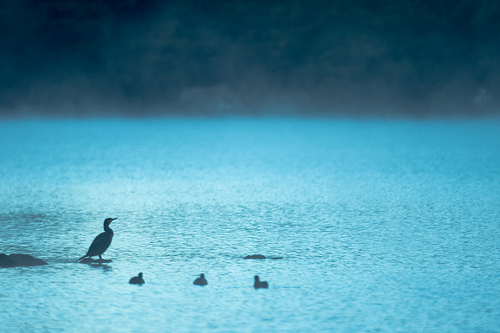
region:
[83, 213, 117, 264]
a duck standing in the water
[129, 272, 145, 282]
a duck sitting in the water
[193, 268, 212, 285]
a duck sitting in the water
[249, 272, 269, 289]
a duck sitting in the water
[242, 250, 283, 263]
a rock in the water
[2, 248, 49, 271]
a rock in the water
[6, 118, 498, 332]
bright blue body of water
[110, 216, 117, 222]
the beak of the duck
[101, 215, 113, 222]
the head of the duck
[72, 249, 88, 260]
the tail of the duck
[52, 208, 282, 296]
Four ducks are in the picture.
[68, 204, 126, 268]
The adult duck is standing on a rock.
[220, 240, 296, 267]
A few rocks are in the water.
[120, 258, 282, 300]
Three ducks are swimming.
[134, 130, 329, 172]
The water is blue.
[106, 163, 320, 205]
The light is reflecting on the water.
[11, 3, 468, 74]
Trees are in the background.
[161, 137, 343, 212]
The water is clear.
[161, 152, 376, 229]
The water is bright.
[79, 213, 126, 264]
grown up duck standing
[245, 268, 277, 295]
baby duck in the water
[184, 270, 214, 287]
baby duck in the water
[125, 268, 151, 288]
baby duck in the water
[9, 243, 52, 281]
rock sitting on the water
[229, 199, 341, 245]
ripples in the water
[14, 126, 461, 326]
multiple ducks in the water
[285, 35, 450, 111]
trees behind the water line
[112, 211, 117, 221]
bill of the duck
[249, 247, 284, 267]
rock protruding from the water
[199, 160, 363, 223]
The water is blue.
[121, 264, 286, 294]
Three ducks are in the water.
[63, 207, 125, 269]
An adult duck.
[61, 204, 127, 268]
The adult is sitting on a rock.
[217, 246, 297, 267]
A few rocks are in the water..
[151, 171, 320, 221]
The light is reflecting in the water.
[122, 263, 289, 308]
The ducks are swimming.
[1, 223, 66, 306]
rock on right in water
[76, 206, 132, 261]
large duck looking over water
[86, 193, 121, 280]
silhouette of large duck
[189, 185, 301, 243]
ripples in blue water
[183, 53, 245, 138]
light spot on brown wall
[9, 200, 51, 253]
dark area in teal water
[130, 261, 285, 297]
3 smaller ducks swimming in blue water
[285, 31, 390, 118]
green and brown foliage in distance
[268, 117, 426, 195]
water is very blue and teal with ripples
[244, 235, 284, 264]
small rock in water